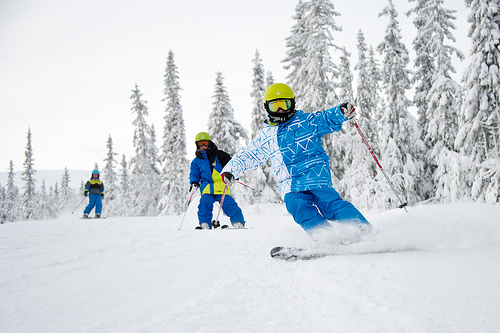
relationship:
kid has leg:
[221, 83, 392, 248] [308, 188, 374, 232]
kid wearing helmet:
[221, 83, 392, 248] [263, 83, 296, 126]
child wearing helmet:
[190, 133, 247, 231] [194, 132, 210, 143]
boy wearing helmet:
[80, 167, 106, 219] [92, 167, 101, 175]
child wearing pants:
[190, 133, 247, 231] [197, 193, 246, 227]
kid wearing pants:
[221, 83, 392, 248] [283, 189, 376, 238]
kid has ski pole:
[221, 83, 392, 248] [352, 116, 408, 214]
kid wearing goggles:
[221, 83, 392, 248] [264, 99, 297, 116]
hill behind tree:
[2, 169, 131, 196] [122, 83, 160, 218]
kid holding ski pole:
[221, 83, 392, 248] [352, 116, 408, 214]